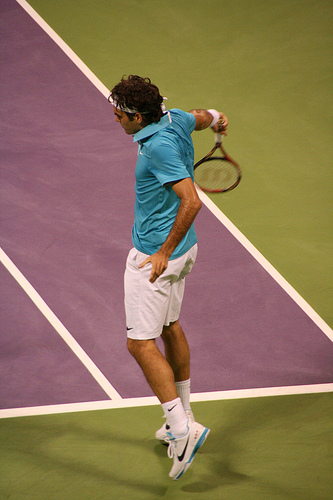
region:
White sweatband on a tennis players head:
[103, 85, 175, 115]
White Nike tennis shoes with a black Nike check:
[153, 415, 210, 479]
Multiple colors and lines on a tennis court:
[201, 375, 308, 405]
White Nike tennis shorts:
[115, 232, 205, 343]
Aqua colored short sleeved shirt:
[117, 106, 212, 254]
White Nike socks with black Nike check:
[156, 376, 201, 437]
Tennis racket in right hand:
[189, 106, 240, 214]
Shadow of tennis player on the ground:
[0, 417, 162, 491]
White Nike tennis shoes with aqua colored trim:
[158, 418, 211, 496]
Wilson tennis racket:
[192, 102, 241, 218]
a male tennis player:
[106, 70, 243, 479]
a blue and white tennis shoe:
[165, 414, 209, 479]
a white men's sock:
[159, 397, 188, 440]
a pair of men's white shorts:
[124, 241, 197, 340]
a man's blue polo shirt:
[132, 110, 200, 254]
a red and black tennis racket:
[187, 116, 243, 195]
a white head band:
[110, 98, 133, 113]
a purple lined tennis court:
[0, 0, 332, 417]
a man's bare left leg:
[124, 335, 178, 403]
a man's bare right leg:
[161, 319, 191, 381]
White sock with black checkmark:
[156, 397, 191, 437]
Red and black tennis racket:
[184, 127, 253, 203]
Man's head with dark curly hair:
[97, 74, 171, 137]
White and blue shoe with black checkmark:
[154, 412, 224, 480]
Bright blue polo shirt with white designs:
[106, 111, 202, 256]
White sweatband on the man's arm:
[204, 106, 220, 130]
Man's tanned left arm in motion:
[129, 178, 216, 287]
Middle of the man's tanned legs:
[109, 328, 206, 406]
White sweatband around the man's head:
[105, 93, 167, 112]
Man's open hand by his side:
[134, 246, 179, 293]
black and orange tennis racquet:
[194, 130, 246, 199]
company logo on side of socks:
[164, 403, 180, 415]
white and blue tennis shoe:
[164, 424, 216, 481]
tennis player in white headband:
[99, 61, 177, 138]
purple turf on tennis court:
[27, 145, 115, 276]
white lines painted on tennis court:
[23, 356, 122, 431]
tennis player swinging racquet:
[92, 49, 275, 352]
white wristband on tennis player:
[201, 104, 220, 131]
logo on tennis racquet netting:
[199, 163, 231, 185]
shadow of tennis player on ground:
[198, 447, 267, 494]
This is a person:
[83, 51, 266, 494]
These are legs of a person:
[127, 275, 217, 489]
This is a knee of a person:
[122, 316, 149, 373]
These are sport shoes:
[154, 400, 216, 483]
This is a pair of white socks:
[151, 363, 191, 439]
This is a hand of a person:
[146, 139, 200, 289]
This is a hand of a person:
[176, 89, 247, 133]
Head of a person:
[77, 43, 167, 149]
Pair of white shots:
[112, 228, 201, 347]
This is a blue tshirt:
[132, 114, 200, 264]